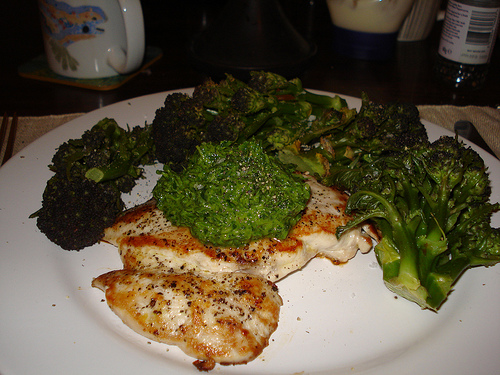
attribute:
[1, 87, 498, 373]
plate — round, white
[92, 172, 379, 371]
meat — cooked, grilled, broiled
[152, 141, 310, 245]
serving — green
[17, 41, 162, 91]
coaster — yellow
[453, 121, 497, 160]
knife — silver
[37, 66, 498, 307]
vegetable — green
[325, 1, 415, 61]
bottle — plastic, clear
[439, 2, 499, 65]
label — white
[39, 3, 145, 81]
cups — white, flowered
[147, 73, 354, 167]
broccoli — cooked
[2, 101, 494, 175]
placemat — beige, white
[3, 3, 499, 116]
table — brown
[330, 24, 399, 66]
lid — blue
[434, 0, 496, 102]
grinder — pepper